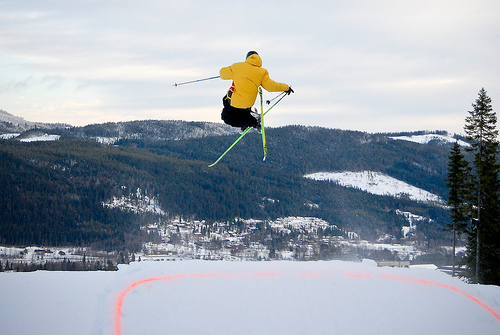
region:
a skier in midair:
[168, 41, 313, 185]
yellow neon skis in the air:
[208, 90, 273, 165]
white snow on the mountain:
[255, 279, 356, 324]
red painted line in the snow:
[106, 273, 160, 330]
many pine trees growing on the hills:
[33, 130, 368, 220]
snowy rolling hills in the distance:
[22, 111, 422, 235]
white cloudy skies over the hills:
[336, 37, 448, 119]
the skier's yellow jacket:
[218, 56, 285, 122]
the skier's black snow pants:
[216, 102, 261, 138]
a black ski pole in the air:
[161, 63, 232, 97]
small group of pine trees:
[445, 89, 499, 281]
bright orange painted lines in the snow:
[106, 262, 495, 333]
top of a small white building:
[368, 257, 414, 269]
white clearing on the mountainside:
[296, 157, 445, 212]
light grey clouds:
[3, 70, 98, 96]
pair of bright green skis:
[208, 85, 288, 172]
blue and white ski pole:
[170, 73, 218, 90]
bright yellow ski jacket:
[222, 54, 294, 108]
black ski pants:
[217, 104, 262, 134]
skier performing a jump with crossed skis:
[162, 46, 297, 170]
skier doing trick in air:
[150, 35, 316, 200]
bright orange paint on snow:
[90, 240, 495, 330]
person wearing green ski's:
[165, 35, 290, 195]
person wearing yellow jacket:
[185, 35, 325, 200]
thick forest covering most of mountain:
[0, 125, 460, 245]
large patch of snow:
[305, 150, 440, 215]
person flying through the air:
[168, 45, 310, 180]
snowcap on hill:
[376, 118, 479, 161]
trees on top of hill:
[440, 149, 492, 279]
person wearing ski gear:
[141, 4, 308, 172]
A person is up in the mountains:
[41, 10, 476, 331]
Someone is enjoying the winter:
[40, 15, 478, 321]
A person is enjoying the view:
[12, 15, 473, 318]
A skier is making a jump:
[35, 23, 471, 319]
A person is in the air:
[56, 6, 457, 316]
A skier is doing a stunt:
[70, 7, 426, 332]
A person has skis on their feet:
[45, 1, 476, 321]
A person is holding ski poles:
[35, 0, 482, 328]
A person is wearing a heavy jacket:
[27, 7, 467, 327]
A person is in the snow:
[12, 15, 487, 319]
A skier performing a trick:
[168, 34, 303, 175]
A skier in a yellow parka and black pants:
[170, 44, 296, 174]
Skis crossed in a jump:
[205, 82, 293, 172]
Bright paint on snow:
[102, 261, 499, 331]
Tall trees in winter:
[439, 83, 496, 288]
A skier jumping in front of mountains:
[0, 43, 496, 278]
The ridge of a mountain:
[3, 99, 472, 160]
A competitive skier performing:
[170, 42, 298, 174]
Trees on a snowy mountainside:
[3, 111, 204, 274]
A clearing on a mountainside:
[298, 164, 450, 206]